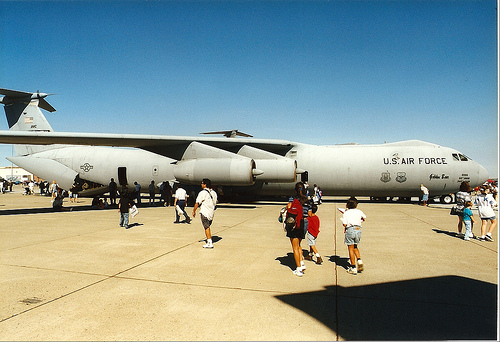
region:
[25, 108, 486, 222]
plane on the ground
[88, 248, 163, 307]
lines on the ground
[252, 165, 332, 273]
woman and a kid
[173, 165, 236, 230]
man on the ground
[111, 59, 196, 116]
sky above the land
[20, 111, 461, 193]
gray military plane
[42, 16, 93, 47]
white clouds in blue sky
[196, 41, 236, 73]
white clouds in blue sky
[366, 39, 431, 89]
white clouds in blue sky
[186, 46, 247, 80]
white clouds in blue sky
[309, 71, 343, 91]
white clouds in blue sky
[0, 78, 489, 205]
a large grey plane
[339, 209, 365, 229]
a young girl wearing a white shirt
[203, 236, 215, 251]
a man wearing a white shoes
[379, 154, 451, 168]
letters painted on a airplane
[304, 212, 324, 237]
a young child wearing a red shirt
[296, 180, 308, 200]
a woman with long hair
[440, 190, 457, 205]
a wheel on a air plane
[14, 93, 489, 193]
gray military plane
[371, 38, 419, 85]
white clouds in blue sky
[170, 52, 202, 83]
white clouds in blue sky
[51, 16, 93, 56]
white clouds in blue sky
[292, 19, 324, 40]
white clouds in blue sky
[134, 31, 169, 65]
white clouds in blue sky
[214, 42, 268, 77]
white clouds in blue sky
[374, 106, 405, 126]
white clouds in blue sky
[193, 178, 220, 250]
a man in a white shirt walking on the tarmac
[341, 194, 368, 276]
a girl in a white shirt and blue jean shorts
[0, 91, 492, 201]
A gray Air Force plane on the tarmac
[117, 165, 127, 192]
an open door on a large airplane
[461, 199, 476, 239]
a small girl in a blue shirt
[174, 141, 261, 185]
an engine on an airplane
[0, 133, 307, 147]
a wing on an air plane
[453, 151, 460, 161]
a cockpit window on an airplane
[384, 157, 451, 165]
the words U.S. AIR FORCE on the side of a plane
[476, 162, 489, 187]
the nose of an airplane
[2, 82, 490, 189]
gray military plane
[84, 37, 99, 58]
white clouds in blue sky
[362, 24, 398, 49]
white clouds in blue sky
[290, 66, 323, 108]
white clouds in blue sky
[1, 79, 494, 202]
aircraft belonging to Air Force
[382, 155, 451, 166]
U.S. Air Force identification marking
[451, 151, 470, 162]
windows for pilots of plane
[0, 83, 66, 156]
tail of military plane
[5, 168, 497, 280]
whole bunch of people walking around military plane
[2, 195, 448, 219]
shadow of military plane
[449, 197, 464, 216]
purse strapped onto woman's shoulders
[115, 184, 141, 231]
woman carrying white bag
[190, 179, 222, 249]
man dressed in casual attire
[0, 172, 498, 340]
tarmac where military plane sits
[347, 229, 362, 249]
blue denim shorts on a child